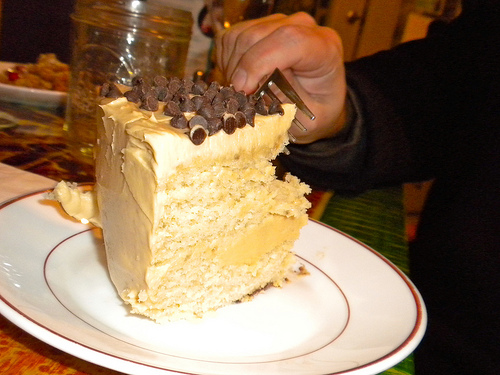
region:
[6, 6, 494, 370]
a person is eating a cake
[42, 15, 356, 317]
a piece of cake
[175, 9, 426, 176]
a fork in hand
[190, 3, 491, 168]
a person's arm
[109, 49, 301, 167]
some chocolate chips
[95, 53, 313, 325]
a cheese cake topped with hershey kisses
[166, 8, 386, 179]
a hand reaching for a piece of cake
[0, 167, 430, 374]
a white plate with cake on it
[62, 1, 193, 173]
an empty glass jar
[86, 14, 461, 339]
a person eats some cake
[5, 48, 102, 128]
a plate of food obscured by a glass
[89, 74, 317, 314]
slice of chocolate topped cake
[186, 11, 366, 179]
a fork is used to slice cake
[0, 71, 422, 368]
a decadent slice of cake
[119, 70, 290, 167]
a layer of hershey kisses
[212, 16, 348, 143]
hand curled around silver fork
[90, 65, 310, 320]
yellow cake topped with chocolate chips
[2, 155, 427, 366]
white plate with dark red rings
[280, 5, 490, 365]
black jacket covering arm and part of body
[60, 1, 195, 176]
light shining on textured glass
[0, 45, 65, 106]
food piled on white plate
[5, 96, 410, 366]
patterned tablecloth under plates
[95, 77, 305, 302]
yellow icing on top and side of cake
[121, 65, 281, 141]
chocolate chips that are sideways, upside down and upright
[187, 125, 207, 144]
chocolate chip on cake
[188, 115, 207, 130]
chocolate chip on cake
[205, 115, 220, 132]
chocolate chip on cake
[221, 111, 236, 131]
chocolate chip on cake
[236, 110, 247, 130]
chocolate chip on cake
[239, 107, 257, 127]
chocolate chip on cake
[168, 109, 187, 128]
chocolate chip on cake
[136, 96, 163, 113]
chocolate chip on cake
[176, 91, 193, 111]
chocolate chip on cake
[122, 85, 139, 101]
chocolate chip on cake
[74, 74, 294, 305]
this is a piece of cake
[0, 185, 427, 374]
this is a plate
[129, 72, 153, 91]
chocolate pieces on the cake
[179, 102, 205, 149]
chocolate pieces on the cake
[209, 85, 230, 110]
chocolate pieces on the cake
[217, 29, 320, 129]
this is a fork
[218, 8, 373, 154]
the hand of a man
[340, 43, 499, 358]
the man has a black coat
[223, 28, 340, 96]
a finger of a man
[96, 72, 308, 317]
triangular slice of cake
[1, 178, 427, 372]
white plate with red border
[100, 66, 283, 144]
chocolate chips on top of cake